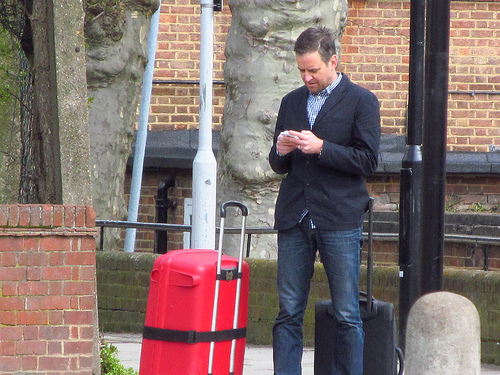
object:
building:
[127, 0, 499, 271]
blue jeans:
[270, 214, 365, 374]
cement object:
[402, 290, 480, 374]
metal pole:
[396, 0, 424, 358]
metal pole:
[423, 0, 446, 297]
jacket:
[268, 74, 380, 234]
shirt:
[307, 73, 344, 130]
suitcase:
[142, 201, 250, 374]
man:
[265, 26, 380, 374]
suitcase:
[318, 196, 399, 374]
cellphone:
[277, 129, 299, 141]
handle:
[351, 193, 389, 303]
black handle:
[215, 201, 250, 219]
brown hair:
[293, 26, 338, 69]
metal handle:
[205, 200, 247, 372]